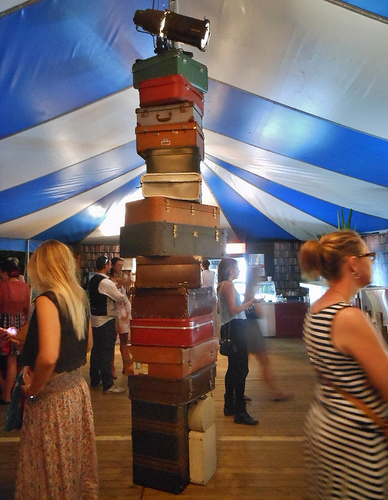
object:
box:
[131, 49, 208, 95]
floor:
[0, 339, 356, 497]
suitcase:
[126, 363, 217, 409]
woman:
[11, 237, 102, 500]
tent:
[0, 0, 388, 242]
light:
[131, 6, 213, 53]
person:
[295, 225, 388, 498]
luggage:
[119, 220, 229, 260]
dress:
[115, 282, 133, 334]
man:
[86, 253, 127, 396]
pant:
[220, 318, 250, 413]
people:
[214, 256, 259, 428]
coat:
[21, 290, 90, 371]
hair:
[25, 236, 90, 341]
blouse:
[14, 366, 103, 500]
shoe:
[233, 401, 259, 427]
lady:
[214, 255, 261, 427]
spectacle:
[132, 5, 212, 54]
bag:
[219, 337, 239, 357]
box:
[187, 423, 218, 486]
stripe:
[301, 445, 387, 480]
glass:
[351, 249, 377, 261]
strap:
[314, 369, 388, 442]